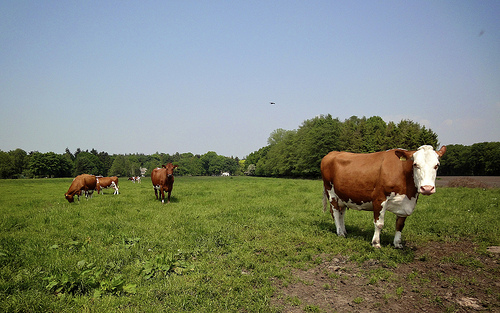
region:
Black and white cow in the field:
[55, 165, 99, 215]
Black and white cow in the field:
[93, 166, 118, 205]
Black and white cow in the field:
[128, 173, 151, 194]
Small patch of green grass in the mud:
[314, 261, 339, 279]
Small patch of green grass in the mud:
[297, 291, 326, 308]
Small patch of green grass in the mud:
[345, 263, 395, 308]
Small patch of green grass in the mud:
[378, 241, 434, 276]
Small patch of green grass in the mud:
[404, 264, 456, 309]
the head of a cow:
[391, 140, 461, 217]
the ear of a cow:
[396, 117, 488, 177]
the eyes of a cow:
[404, 150, 454, 173]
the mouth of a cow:
[402, 177, 442, 207]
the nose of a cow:
[410, 176, 447, 199]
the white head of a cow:
[401, 130, 461, 202]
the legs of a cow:
[361, 201, 421, 265]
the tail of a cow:
[309, 136, 360, 222]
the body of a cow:
[314, 118, 488, 220]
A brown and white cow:
[315, 143, 437, 251]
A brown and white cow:
[145, 158, 186, 211]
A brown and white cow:
[93, 167, 129, 202]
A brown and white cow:
[126, 173, 150, 194]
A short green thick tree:
[201, 150, 236, 185]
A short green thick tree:
[105, 149, 133, 169]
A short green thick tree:
[265, 119, 293, 171]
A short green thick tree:
[1, 145, 16, 177]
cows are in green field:
[8, 54, 497, 279]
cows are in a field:
[47, 140, 450, 252]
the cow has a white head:
[393, 135, 450, 199]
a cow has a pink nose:
[418, 182, 437, 195]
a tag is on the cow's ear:
[388, 143, 414, 167]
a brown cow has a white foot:
[143, 159, 183, 210]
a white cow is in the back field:
[218, 167, 233, 181]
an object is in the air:
[258, 90, 286, 113]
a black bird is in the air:
[261, 95, 285, 110]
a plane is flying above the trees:
[261, 95, 283, 112]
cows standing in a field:
[9, 79, 498, 307]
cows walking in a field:
[87, 98, 484, 255]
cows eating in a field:
[44, 136, 199, 246]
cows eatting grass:
[78, 176, 97, 193]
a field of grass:
[19, 144, 397, 311]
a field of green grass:
[28, 173, 328, 306]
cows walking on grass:
[42, 97, 482, 247]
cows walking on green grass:
[48, 126, 408, 310]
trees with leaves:
[280, 98, 455, 233]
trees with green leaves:
[272, 107, 434, 182]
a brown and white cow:
[319, 145, 447, 249]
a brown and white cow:
[93, 173, 122, 195]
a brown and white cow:
[126, 173, 145, 185]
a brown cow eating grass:
[60, 173, 101, 205]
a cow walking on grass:
[148, 163, 180, 204]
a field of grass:
[3, 173, 498, 311]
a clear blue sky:
[0, 0, 495, 145]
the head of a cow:
[395, 143, 450, 196]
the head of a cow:
[163, 162, 177, 179]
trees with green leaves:
[1, 115, 498, 179]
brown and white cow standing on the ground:
[314, 140, 453, 255]